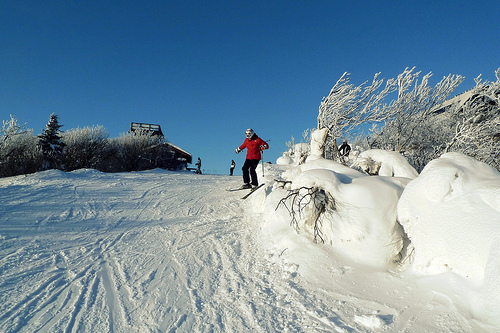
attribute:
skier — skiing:
[226, 122, 273, 198]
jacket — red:
[240, 137, 272, 160]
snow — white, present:
[1, 169, 498, 332]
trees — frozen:
[319, 67, 391, 156]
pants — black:
[242, 157, 259, 190]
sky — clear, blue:
[0, 0, 499, 125]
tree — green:
[41, 108, 65, 164]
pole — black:
[260, 147, 270, 180]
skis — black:
[226, 181, 268, 201]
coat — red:
[237, 131, 268, 163]